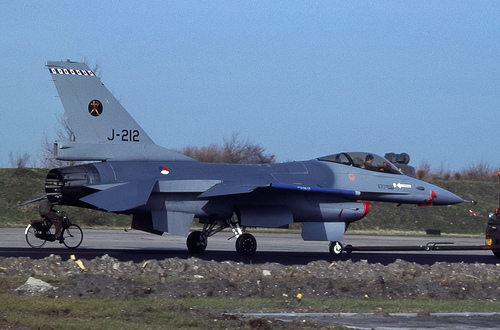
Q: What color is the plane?
A: Blue.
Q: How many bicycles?
A: One.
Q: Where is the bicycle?
A: Behind the plane.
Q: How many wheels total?
A: Five.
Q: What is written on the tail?
A: J-212.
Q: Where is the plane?
A: Landing strip.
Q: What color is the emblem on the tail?
A: Black and yellow.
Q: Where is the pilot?
A: In the cockpit.